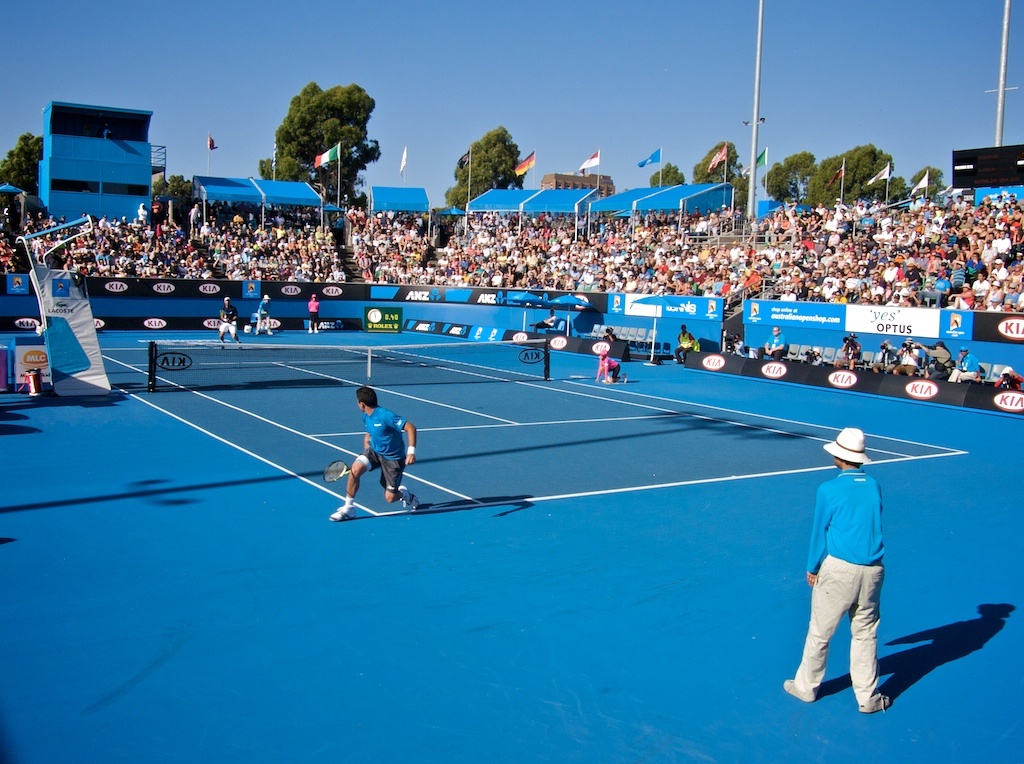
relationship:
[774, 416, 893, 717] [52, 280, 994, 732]
man standing at court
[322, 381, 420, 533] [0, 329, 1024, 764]
person playing court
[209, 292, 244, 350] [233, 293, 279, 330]
man waiting for ball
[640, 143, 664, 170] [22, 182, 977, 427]
flag above stands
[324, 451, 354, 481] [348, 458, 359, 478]
racket in hands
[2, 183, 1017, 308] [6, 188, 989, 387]
crowd in stands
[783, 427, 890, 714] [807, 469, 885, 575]
man dressed in shirt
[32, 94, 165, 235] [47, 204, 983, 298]
area above crowd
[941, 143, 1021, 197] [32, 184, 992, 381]
scoreboard above crowd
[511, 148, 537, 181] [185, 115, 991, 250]
flag in stands